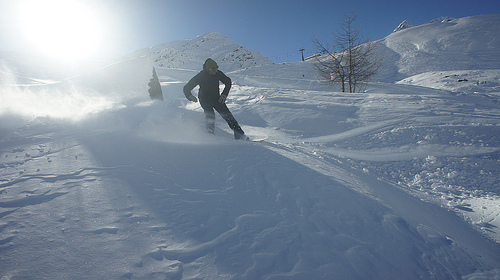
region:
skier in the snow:
[175, 48, 262, 153]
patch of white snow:
[462, 171, 479, 186]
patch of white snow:
[414, 118, 434, 133]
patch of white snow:
[386, 145, 402, 165]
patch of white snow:
[64, 175, 81, 190]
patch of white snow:
[407, 95, 430, 101]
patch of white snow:
[344, 126, 359, 147]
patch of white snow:
[313, 133, 322, 153]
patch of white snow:
[458, 201, 468, 218]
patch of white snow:
[78, 131, 106, 157]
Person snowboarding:
[171, 52, 264, 147]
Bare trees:
[307, 5, 391, 101]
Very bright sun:
[7, 0, 114, 70]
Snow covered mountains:
[3, 11, 498, 277]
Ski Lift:
[233, 45, 313, 65]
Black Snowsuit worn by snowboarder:
[176, 55, 252, 135]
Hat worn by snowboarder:
[195, 57, 225, 70]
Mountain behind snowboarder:
[127, 27, 282, 73]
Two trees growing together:
[301, 12, 391, 98]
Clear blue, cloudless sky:
[1, 0, 498, 72]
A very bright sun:
[1, 0, 143, 94]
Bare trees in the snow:
[310, 8, 382, 98]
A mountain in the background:
[122, 30, 288, 75]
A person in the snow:
[179, 54, 267, 144]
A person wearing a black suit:
[182, 56, 242, 132]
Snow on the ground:
[5, 16, 495, 273]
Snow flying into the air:
[120, 100, 266, 145]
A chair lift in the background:
[264, 46, 312, 65]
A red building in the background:
[303, 49, 322, 63]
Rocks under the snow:
[147, 36, 264, 68]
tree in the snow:
[319, 43, 348, 95]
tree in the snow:
[339, 18, 374, 101]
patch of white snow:
[426, 181, 460, 196]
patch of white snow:
[368, 125, 380, 140]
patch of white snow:
[71, 236, 85, 252]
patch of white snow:
[83, 192, 100, 210]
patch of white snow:
[283, 120, 305, 144]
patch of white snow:
[398, 131, 417, 153]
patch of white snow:
[324, 130, 333, 147]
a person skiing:
[97, 30, 403, 266]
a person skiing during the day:
[140, 31, 332, 235]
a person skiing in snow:
[130, 20, 418, 279]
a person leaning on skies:
[151, 38, 398, 263]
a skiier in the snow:
[149, 51, 399, 250]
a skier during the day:
[144, 18, 331, 187]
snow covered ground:
[314, 155, 494, 260]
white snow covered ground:
[284, 72, 497, 269]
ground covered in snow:
[269, 81, 485, 279]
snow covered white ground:
[276, 83, 499, 244]